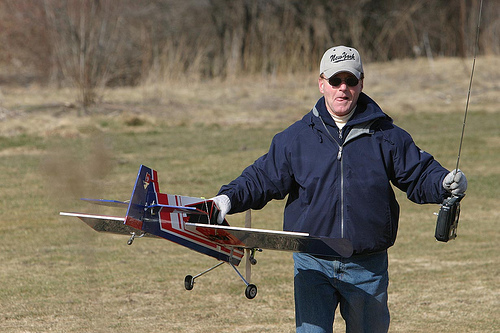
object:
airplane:
[58, 166, 355, 298]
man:
[207, 46, 468, 332]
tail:
[83, 166, 205, 231]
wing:
[189, 221, 356, 263]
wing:
[60, 210, 158, 239]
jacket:
[218, 91, 453, 262]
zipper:
[338, 145, 344, 241]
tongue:
[335, 97, 344, 101]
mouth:
[334, 93, 348, 102]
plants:
[137, 34, 224, 90]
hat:
[318, 45, 364, 84]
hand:
[207, 194, 232, 222]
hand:
[440, 168, 469, 201]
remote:
[433, 1, 485, 244]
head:
[316, 46, 367, 119]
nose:
[340, 83, 347, 93]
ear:
[318, 79, 326, 94]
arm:
[217, 115, 304, 214]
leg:
[343, 255, 392, 333]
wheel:
[244, 283, 257, 300]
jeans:
[290, 247, 392, 333]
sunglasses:
[321, 72, 363, 87]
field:
[0, 56, 497, 331]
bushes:
[1, 2, 498, 88]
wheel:
[183, 273, 196, 294]